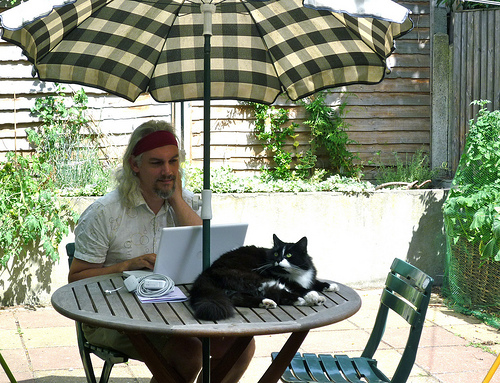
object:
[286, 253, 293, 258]
eye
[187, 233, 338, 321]
cat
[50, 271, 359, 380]
outdoor table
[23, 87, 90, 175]
ivy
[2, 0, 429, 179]
wall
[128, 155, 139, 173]
ear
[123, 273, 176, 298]
charger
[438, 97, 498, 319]
plant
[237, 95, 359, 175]
plant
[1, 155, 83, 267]
plant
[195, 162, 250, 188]
plant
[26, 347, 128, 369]
pavers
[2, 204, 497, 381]
patio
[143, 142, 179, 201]
face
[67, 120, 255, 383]
man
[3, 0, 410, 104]
umbrella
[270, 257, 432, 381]
green chair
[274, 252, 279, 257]
eye